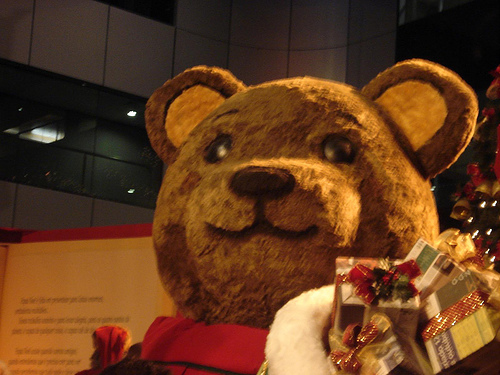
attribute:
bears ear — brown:
[378, 67, 475, 163]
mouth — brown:
[204, 201, 319, 241]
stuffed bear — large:
[74, 56, 479, 373]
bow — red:
[327, 255, 428, 313]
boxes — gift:
[289, 235, 499, 372]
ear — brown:
[358, 53, 486, 185]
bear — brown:
[77, 54, 491, 373]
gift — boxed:
[329, 256, 420, 341]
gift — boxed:
[395, 290, 495, 374]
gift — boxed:
[328, 312, 405, 372]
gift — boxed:
[403, 237, 478, 319]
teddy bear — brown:
[83, 59, 483, 373]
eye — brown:
[317, 110, 409, 177]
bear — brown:
[149, 51, 476, 350]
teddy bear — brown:
[118, 57, 479, 319]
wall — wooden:
[0, 236, 180, 371]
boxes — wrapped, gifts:
[304, 221, 498, 373]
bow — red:
[358, 258, 426, 309]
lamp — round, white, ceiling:
[123, 108, 138, 118]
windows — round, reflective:
[1, 66, 167, 216]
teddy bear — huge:
[132, 79, 486, 333]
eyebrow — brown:
[333, 105, 365, 132]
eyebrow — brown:
[205, 105, 239, 124]